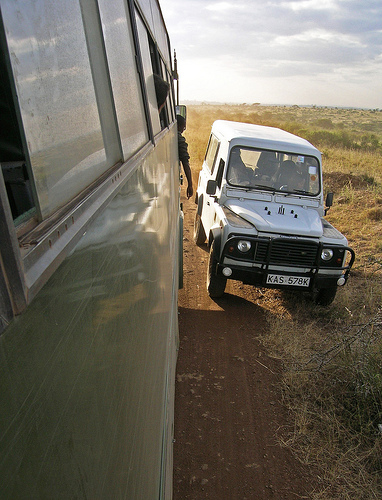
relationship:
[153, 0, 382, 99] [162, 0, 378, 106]
white cloud in blue sky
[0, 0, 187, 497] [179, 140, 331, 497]
bus on dirt road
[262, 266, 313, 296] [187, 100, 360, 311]
license plate on jeep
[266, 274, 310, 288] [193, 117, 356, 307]
license plate in front of jeep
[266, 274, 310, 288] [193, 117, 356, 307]
license plate on jeep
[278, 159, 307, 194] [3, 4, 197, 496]
man leaning from bus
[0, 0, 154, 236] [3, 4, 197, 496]
windows are on bus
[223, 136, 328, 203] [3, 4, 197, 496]
windows are on bus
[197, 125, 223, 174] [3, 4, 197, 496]
windows are on bus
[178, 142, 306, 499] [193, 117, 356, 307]
dirt road lying jeep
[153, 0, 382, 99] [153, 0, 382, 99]
white cloud floating white cloud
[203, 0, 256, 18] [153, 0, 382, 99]
white cloud moving white cloud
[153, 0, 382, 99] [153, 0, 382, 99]
white cloud disappearing white cloud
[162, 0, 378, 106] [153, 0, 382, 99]
blue sky protecting white cloud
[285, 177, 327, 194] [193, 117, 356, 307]
man sitting jeep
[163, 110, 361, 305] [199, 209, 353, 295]
jeep parked headlights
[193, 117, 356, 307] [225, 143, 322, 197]
jeep parked windshield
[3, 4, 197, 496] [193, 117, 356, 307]
bus passing jeep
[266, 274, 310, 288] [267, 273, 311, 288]
license plate mounted black white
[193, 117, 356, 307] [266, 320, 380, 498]
jeep parked grass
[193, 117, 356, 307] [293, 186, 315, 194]
jeep parked windshield wipers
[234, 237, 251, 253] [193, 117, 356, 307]
light installed jeep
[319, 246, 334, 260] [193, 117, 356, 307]
light mounted jeep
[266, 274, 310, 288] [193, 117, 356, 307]
license plate mounted jeep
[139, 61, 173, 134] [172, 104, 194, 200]
men walking man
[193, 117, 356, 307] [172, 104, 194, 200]
jeep parked man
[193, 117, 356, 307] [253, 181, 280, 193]
jeep parked windshield wipers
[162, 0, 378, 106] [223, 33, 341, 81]
blue sky protecting clouds